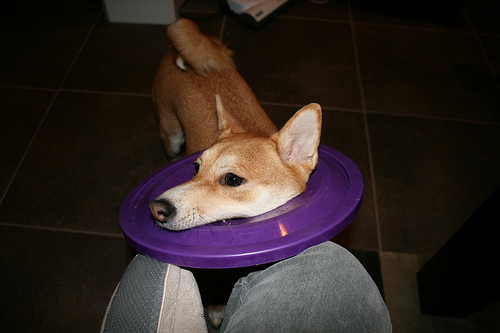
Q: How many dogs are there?
A: One.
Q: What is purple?
A: Frisbee.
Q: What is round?
A: Frisbee.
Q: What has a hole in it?
A: A frisbee.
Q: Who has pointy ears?
A: The dog.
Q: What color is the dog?
A: Brown.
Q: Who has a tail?
A: Dog.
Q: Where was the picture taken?
A: Wearing the frisbee.